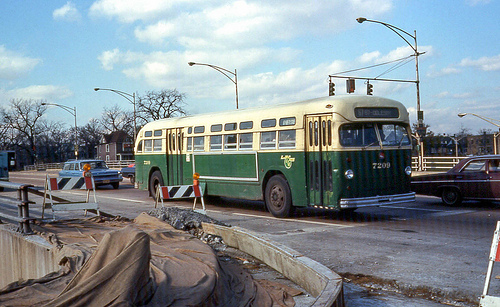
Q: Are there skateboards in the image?
A: No, there are no skateboards.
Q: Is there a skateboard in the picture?
A: No, there are no skateboards.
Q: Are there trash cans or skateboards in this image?
A: No, there are no skateboards or trash cans.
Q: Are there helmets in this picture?
A: No, there are no helmets.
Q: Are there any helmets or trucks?
A: No, there are no helmets or trucks.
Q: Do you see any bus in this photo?
A: Yes, there is a bus.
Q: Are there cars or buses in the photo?
A: Yes, there is a bus.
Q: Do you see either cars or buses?
A: Yes, there is a bus.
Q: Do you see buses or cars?
A: Yes, there is a bus.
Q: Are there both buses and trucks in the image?
A: No, there is a bus but no trucks.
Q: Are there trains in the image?
A: No, there are no trains.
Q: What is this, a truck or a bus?
A: This is a bus.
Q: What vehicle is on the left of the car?
A: The vehicle is a bus.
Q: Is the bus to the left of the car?
A: Yes, the bus is to the left of the car.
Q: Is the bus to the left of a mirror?
A: No, the bus is to the left of the car.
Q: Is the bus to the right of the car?
A: No, the bus is to the left of the car.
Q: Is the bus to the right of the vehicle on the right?
A: No, the bus is to the left of the car.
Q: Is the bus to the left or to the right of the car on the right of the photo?
A: The bus is to the left of the car.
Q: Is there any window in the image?
A: Yes, there is a window.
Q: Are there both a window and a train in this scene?
A: No, there is a window but no trains.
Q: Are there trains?
A: No, there are no trains.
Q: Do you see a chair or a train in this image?
A: No, there are no trains or chairs.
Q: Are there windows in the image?
A: Yes, there is a window.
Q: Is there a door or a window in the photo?
A: Yes, there is a window.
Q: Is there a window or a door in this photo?
A: Yes, there is a window.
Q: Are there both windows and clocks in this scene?
A: No, there is a window but no clocks.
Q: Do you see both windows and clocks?
A: No, there is a window but no clocks.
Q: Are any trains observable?
A: No, there are no trains.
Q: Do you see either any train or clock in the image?
A: No, there are no trains or clocks.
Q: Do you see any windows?
A: Yes, there is a window.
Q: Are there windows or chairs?
A: Yes, there is a window.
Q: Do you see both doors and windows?
A: Yes, there are both a window and a door.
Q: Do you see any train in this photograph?
A: No, there are no trains.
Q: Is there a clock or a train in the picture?
A: No, there are no trains or clocks.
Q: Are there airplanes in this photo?
A: No, there are no airplanes.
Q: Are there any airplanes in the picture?
A: No, there are no airplanes.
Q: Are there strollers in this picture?
A: No, there are no strollers.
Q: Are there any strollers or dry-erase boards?
A: No, there are no strollers or dry-erase boards.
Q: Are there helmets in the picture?
A: No, there are no helmets.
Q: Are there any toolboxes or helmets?
A: No, there are no helmets or toolboxes.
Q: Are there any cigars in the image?
A: No, there are no cigars.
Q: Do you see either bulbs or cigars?
A: No, there are no cigars or bulbs.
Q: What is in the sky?
A: The clouds are in the sky.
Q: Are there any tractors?
A: No, there are no tractors.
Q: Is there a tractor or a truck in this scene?
A: No, there are no tractors or trucks.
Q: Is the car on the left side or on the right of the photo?
A: The car is on the right of the image.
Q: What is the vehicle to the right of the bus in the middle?
A: The vehicle is a car.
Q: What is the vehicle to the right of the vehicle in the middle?
A: The vehicle is a car.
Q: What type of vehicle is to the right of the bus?
A: The vehicle is a car.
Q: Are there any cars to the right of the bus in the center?
A: Yes, there is a car to the right of the bus.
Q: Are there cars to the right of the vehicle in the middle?
A: Yes, there is a car to the right of the bus.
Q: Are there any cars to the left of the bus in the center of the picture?
A: No, the car is to the right of the bus.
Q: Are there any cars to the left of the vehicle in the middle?
A: No, the car is to the right of the bus.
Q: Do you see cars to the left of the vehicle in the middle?
A: No, the car is to the right of the bus.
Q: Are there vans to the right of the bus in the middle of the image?
A: No, there is a car to the right of the bus.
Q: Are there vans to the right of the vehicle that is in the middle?
A: No, there is a car to the right of the bus.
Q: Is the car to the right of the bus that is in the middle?
A: Yes, the car is to the right of the bus.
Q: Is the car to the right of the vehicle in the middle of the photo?
A: Yes, the car is to the right of the bus.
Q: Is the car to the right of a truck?
A: No, the car is to the right of the bus.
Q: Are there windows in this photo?
A: Yes, there is a window.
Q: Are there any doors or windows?
A: Yes, there is a window.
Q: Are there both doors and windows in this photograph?
A: Yes, there are both a window and a door.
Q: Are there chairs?
A: No, there are no chairs.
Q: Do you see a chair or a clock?
A: No, there are no chairs or clocks.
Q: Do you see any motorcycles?
A: No, there are no motorcycles.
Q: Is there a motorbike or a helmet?
A: No, there are no motorcycles or helmets.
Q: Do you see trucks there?
A: No, there are no trucks.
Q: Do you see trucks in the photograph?
A: No, there are no trucks.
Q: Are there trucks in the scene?
A: No, there are no trucks.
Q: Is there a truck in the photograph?
A: No, there are no trucks.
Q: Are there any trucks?
A: No, there are no trucks.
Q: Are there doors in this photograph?
A: Yes, there are doors.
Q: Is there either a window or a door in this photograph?
A: Yes, there are doors.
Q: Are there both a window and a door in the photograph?
A: Yes, there are both a door and a window.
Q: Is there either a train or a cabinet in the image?
A: No, there are no trains or cabinets.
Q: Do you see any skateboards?
A: No, there are no skateboards.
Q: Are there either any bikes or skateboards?
A: No, there are no skateboards or bikes.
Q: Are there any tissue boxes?
A: No, there are no tissue boxes.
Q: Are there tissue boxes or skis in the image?
A: No, there are no tissue boxes or skis.